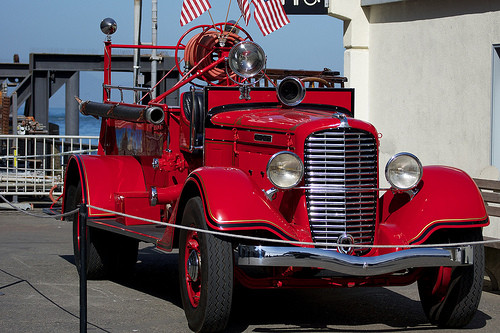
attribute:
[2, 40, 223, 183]
structure — gray, beam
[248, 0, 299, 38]
flag — american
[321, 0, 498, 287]
building — white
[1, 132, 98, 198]
white fence — metal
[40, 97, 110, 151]
water — blue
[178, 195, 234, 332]
tire — thin, rubber, black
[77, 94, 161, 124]
pole — black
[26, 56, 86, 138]
pillars — metal, dock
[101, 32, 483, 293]
car — old, red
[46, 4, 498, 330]
fire truck — vintage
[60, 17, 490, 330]
car — old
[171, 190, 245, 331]
wheels — red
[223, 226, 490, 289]
bumper — chrome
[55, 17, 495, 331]
truck — red, bright, parked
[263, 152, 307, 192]
headlight — circular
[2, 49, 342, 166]
beams — gray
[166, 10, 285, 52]
flags — american